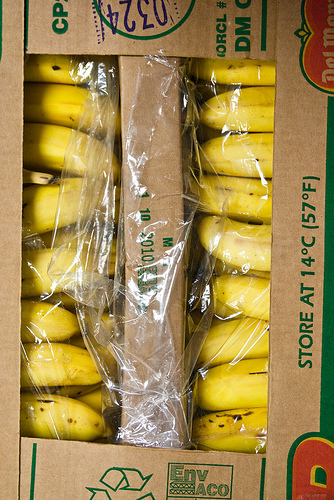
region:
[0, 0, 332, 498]
The box is filled with bananas.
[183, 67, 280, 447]
The group of bananas is yellow.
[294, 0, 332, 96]
The box has a logo.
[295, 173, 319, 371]
Green letters and numbers are on the box.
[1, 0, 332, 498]
The box of bananas is made of brown cardboard.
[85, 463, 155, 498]
A recycle symbol is on the box.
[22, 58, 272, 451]
Plastic covers the bananas where the box is opened.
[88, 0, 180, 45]
Numbers are stamped in purple on the box.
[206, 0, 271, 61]
Green lettering is on the brown box.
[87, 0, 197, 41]
A green circle is behind the purple numbers.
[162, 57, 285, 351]
Bananas in a card board box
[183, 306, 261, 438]
Bananas in a card board box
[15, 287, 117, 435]
Bananas in a card board box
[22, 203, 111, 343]
Bananas in a card board box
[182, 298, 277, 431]
Bananas in a card board box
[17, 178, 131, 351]
Bananas in a card board box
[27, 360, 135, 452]
Bananas in a card board box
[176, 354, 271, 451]
Bananas in a card board box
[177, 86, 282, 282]
Bananas in a card board box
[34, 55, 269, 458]
yellow bananas in box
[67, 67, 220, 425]
clear plastic in box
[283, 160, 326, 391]
green storage instructions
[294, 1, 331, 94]
red and white logo on box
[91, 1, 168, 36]
blue numbers on box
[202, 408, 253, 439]
brown spot on banana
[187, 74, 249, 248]
yellow flesh on banana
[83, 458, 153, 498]
green recycle sign on box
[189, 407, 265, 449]
banana in the box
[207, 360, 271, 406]
banana in the box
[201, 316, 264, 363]
banana in the box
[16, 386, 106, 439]
banana in the box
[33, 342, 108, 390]
banana in the box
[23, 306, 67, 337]
banana in the box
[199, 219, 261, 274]
banana in the box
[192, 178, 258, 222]
banana in the box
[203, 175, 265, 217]
banana in the box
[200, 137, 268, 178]
banana in the box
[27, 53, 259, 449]
yellow bananas in box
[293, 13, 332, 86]
red and white logo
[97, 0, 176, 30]
blue numbers on box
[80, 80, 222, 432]
plastic wrap in box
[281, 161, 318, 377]
green instructions on box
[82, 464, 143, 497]
green recycle symbol on box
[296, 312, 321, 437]
box is light brown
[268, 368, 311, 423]
box is cardboard